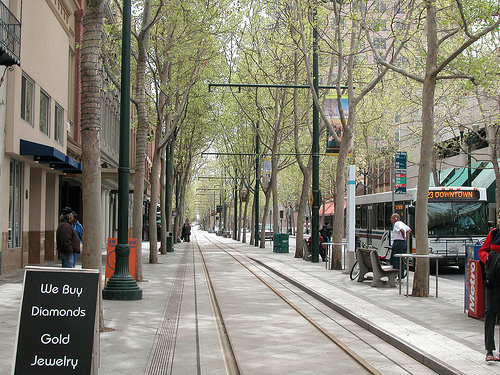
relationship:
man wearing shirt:
[389, 212, 413, 286] [390, 221, 412, 241]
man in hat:
[55, 205, 83, 268] [61, 204, 77, 218]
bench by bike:
[353, 246, 400, 289] [350, 235, 394, 281]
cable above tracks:
[206, 79, 356, 99] [191, 226, 466, 374]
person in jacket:
[476, 212, 499, 368] [478, 228, 500, 286]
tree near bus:
[362, 0, 500, 308] [343, 185, 487, 279]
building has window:
[1, 1, 85, 275] [20, 69, 39, 130]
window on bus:
[375, 200, 383, 230] [343, 185, 487, 279]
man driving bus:
[455, 208, 476, 233] [343, 185, 487, 279]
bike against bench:
[350, 235, 394, 281] [353, 246, 400, 289]